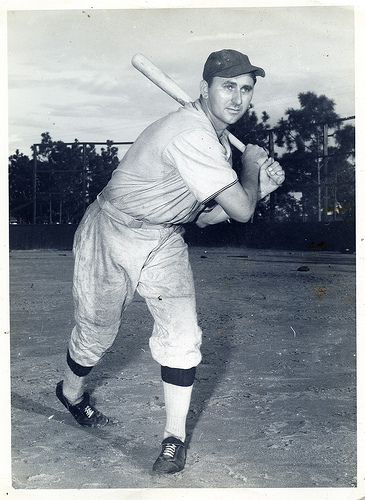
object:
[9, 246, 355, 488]
ground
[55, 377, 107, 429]
shoe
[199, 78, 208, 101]
ear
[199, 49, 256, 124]
head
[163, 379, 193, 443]
sock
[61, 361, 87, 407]
sock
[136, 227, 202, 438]
leg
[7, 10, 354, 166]
sky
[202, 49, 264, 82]
hat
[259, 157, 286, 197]
hand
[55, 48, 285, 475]
person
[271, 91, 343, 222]
trees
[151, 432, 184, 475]
feet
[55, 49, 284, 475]
man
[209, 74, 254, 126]
face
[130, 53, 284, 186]
bat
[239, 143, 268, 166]
hand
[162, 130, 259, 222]
arm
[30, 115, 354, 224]
fence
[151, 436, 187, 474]
shoe